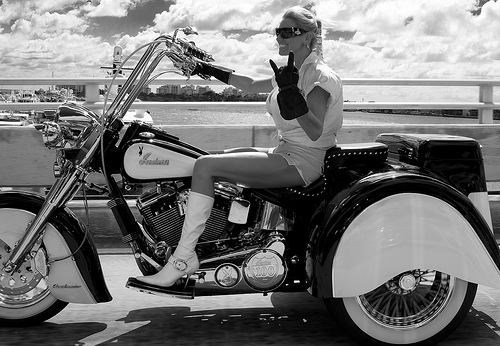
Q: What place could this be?
A: It is a road.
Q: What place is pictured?
A: It is a road.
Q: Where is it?
A: This is at the road.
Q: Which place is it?
A: It is a road.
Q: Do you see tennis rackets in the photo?
A: No, there are no tennis rackets.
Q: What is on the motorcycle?
A: The logo is on the motorcycle.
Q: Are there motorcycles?
A: Yes, there is a motorcycle.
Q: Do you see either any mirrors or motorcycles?
A: Yes, there is a motorcycle.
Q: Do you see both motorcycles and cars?
A: No, there is a motorcycle but no cars.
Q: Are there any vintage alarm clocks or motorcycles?
A: Yes, there is a vintage motorcycle.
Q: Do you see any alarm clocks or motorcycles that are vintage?
A: Yes, the motorcycle is vintage.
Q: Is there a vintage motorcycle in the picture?
A: Yes, there is a vintage motorcycle.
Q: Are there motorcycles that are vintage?
A: Yes, there is a motorcycle that is vintage.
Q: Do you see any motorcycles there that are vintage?
A: Yes, there is a motorcycle that is vintage.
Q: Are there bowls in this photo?
A: No, there are no bowls.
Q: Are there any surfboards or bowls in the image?
A: No, there are no bowls or surfboards.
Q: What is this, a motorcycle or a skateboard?
A: This is a motorcycle.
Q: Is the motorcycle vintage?
A: Yes, the motorcycle is vintage.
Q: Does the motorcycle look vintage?
A: Yes, the motorcycle is vintage.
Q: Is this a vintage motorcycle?
A: Yes, this is a vintage motorcycle.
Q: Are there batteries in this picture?
A: No, there are no batteries.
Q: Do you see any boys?
A: No, there are no boys.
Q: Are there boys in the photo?
A: No, there are no boys.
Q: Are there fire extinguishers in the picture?
A: No, there are no fire extinguishers.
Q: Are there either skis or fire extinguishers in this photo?
A: No, there are no fire extinguishers or skis.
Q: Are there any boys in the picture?
A: No, there are no boys.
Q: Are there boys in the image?
A: No, there are no boys.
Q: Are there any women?
A: Yes, there is a woman.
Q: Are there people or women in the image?
A: Yes, there is a woman.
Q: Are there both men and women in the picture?
A: No, there is a woman but no men.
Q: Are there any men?
A: No, there are no men.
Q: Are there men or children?
A: No, there are no men or children.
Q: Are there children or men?
A: No, there are no men or children.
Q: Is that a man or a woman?
A: That is a woman.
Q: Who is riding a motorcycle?
A: The woman is riding a motorcycle.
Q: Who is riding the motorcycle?
A: The woman is riding a motorcycle.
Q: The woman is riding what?
A: The woman is riding a motorcycle.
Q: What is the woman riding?
A: The woman is riding a motorcycle.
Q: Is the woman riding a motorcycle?
A: Yes, the woman is riding a motorcycle.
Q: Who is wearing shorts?
A: The woman is wearing shorts.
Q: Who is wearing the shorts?
A: The woman is wearing shorts.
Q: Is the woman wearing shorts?
A: Yes, the woman is wearing shorts.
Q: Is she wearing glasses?
A: No, the woman is wearing shorts.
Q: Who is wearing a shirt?
A: The woman is wearing a shirt.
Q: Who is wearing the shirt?
A: The woman is wearing a shirt.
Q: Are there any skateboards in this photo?
A: No, there are no skateboards.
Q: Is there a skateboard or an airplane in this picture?
A: No, there are no skateboards or airplanes.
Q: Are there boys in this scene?
A: No, there are no boys.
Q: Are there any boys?
A: No, there are no boys.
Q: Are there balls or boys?
A: No, there are no boys or balls.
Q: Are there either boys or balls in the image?
A: No, there are no boys or balls.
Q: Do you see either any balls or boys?
A: No, there are no boys or balls.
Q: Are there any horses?
A: No, there are no horses.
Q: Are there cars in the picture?
A: No, there are no cars.